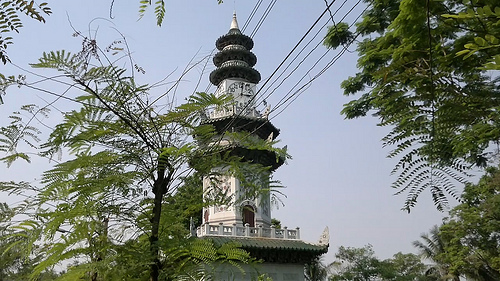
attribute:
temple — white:
[208, 21, 295, 243]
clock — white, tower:
[229, 79, 253, 106]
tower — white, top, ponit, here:
[215, 37, 255, 67]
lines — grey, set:
[271, 27, 328, 91]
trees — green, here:
[422, 51, 476, 93]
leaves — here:
[25, 6, 48, 14]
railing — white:
[238, 225, 276, 246]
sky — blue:
[156, 24, 177, 33]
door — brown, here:
[228, 201, 262, 227]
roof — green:
[269, 237, 324, 255]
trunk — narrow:
[122, 245, 183, 273]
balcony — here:
[181, 212, 250, 238]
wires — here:
[267, 42, 313, 75]